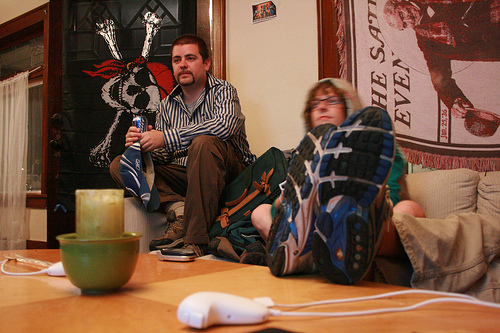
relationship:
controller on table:
[178, 275, 266, 332] [150, 255, 180, 316]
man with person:
[128, 39, 240, 187] [249, 74, 429, 287]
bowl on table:
[59, 198, 140, 291] [150, 255, 180, 316]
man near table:
[128, 39, 240, 187] [150, 255, 180, 316]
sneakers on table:
[336, 115, 383, 271] [150, 255, 180, 316]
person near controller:
[249, 74, 429, 287] [178, 275, 266, 332]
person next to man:
[249, 74, 429, 287] [128, 39, 240, 187]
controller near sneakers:
[178, 275, 266, 332] [336, 115, 383, 271]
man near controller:
[128, 39, 240, 187] [178, 275, 266, 332]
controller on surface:
[173, 288, 282, 331] [5, 240, 483, 323]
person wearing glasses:
[245, 74, 413, 286] [304, 93, 342, 105]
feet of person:
[265, 110, 389, 292] [255, 78, 422, 286]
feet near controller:
[265, 110, 389, 292] [178, 275, 266, 332]